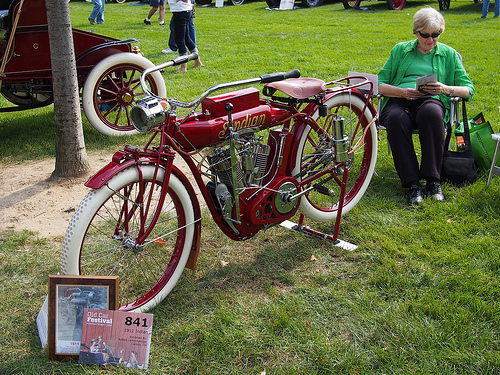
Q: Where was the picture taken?
A: In a park.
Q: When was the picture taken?
A: During the day.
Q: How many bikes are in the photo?
A: One.